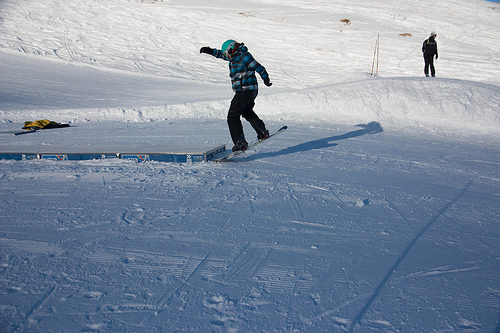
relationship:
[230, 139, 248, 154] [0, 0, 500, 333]
shoe pints in snow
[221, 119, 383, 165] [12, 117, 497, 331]
shadow cast on ground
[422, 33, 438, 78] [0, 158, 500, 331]
man stands on snow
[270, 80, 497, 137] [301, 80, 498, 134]
snow on hill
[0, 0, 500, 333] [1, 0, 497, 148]
snow on hill side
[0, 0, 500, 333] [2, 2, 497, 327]
snow on hillside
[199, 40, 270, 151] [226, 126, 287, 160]
man in board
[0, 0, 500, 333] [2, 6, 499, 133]
snow on hill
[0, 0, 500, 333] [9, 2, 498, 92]
snow on hill side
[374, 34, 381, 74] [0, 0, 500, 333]
psticks on snow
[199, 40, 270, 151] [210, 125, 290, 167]
man on a snowboard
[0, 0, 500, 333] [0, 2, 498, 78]
snow on hillside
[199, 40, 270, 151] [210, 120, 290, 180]
man on board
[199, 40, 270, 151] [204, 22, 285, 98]
man wears coat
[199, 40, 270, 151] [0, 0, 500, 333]
man in snow